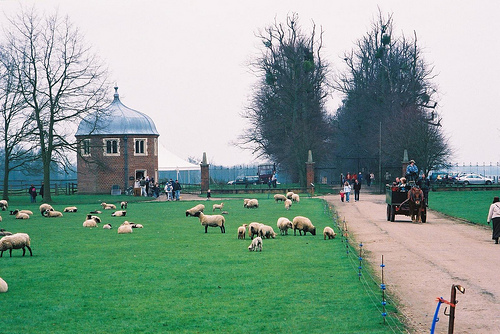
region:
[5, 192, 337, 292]
Sheep on a green field.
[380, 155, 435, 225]
People riding on a horse drawn farm carriage.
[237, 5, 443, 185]
Two tall scary trees.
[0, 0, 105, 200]
Leafless tall trees on the field.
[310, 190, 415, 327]
One side of the field is fenced.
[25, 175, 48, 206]
People chatting under the tree.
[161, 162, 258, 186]
High lined fence in the background.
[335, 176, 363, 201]
Family walking along the path.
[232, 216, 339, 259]
Sheep eating grass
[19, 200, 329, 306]
Sheep in a large green pasture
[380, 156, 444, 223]
People in a horse drawn wagon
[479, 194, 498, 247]
Person walking down a dirt road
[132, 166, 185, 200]
People standing outside a building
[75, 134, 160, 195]
Red brick building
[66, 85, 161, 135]
Silver dome roof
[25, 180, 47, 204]
People standing under a tree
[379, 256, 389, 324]
Blue ribbons on a fence post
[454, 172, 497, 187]
Silver car parked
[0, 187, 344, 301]
sheeps on a green field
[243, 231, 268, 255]
a lamb is eating grass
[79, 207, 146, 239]
sheeps are lying on the grass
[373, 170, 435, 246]
a cart is pulling by a horse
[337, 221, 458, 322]
a fence on side a field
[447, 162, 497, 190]
a car on the road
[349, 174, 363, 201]
man wearing black cloths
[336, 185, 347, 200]
a kid wears red top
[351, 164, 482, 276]
a cart on an unpaved road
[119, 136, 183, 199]
people in front a building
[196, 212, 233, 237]
sheep on the grass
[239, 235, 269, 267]
sheep on the grass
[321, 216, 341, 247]
sheep on the grass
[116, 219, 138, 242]
sheep on the grass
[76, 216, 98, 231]
sheep on the grass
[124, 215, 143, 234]
sheep on the grass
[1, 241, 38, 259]
sheep on the grass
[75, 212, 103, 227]
sheep on the grass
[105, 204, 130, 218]
sheep on the grass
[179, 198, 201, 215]
sheep on the grass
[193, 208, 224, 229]
white sheep on the green grass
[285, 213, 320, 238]
white sheep on the green grass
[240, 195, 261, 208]
white sheep on the green grass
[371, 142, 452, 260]
Man pulling a wagon with a horse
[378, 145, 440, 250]
Man riding down the dirt road next to the sheep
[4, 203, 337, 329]
several sheep grazing on the lawn on the farm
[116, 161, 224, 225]
Several people watching the animals in the yard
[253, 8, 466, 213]
Tall trees with no leaves next to the house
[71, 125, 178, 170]
Three windows at the top of the building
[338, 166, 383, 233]
Small family walking down the dirt road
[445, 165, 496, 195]
Silver car parked in the rear of the parking lot